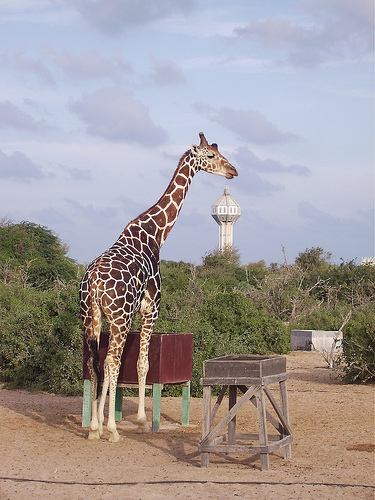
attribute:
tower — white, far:
[213, 186, 242, 257]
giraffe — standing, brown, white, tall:
[76, 131, 241, 442]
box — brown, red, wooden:
[84, 330, 196, 387]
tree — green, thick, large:
[0, 219, 82, 388]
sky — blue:
[0, 0, 375, 270]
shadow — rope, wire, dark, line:
[1, 476, 374, 490]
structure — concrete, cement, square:
[290, 330, 343, 355]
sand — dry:
[0, 350, 375, 499]